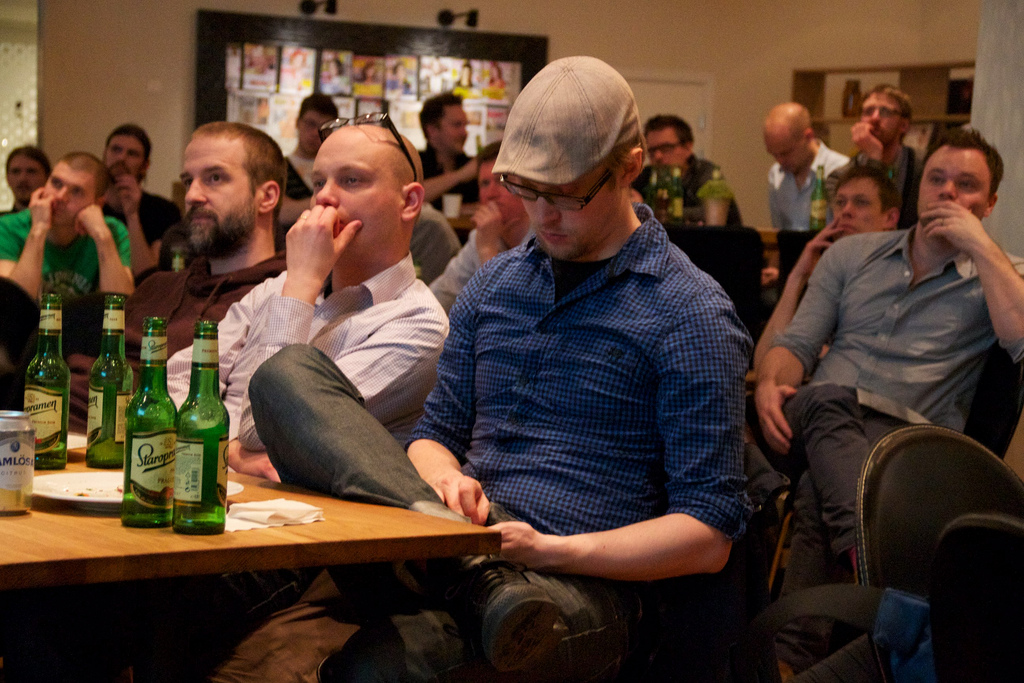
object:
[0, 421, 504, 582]
table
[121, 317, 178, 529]
beer bottle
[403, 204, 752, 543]
shirt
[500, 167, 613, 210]
eyeglasses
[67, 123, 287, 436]
man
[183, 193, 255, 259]
beard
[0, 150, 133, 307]
man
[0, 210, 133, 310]
shirt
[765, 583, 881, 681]
back pack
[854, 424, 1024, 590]
chair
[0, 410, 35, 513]
beer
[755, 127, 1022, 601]
man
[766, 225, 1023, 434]
shirt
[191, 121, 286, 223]
blonde hair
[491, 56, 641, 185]
hat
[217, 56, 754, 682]
man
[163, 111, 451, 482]
man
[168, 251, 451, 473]
white shirt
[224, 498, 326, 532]
napkin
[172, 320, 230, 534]
beer bottle